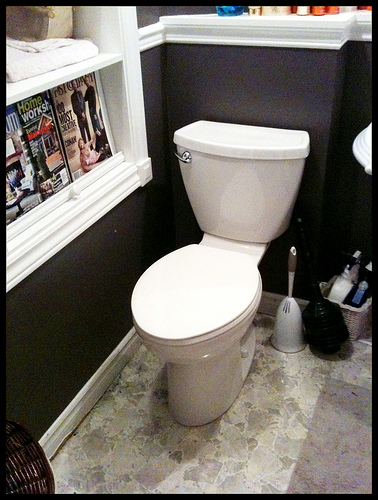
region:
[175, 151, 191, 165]
CROME HANDLE ON THE TOILET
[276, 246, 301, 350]
TOILET BOWL BRUSH CLEANER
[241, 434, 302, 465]
TILE ON THE FLOOR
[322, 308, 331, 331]
BLACK PLUNGIE ON THE FLOOR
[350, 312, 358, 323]
STRAW BASKET ON THE FLOOR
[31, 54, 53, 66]
WHITE TOWEL ON THE SHELF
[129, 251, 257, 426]
A white clean toilet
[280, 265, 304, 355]
A white clean toilet brush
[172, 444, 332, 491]
A white clean toilet floor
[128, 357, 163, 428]
A white clean toilet floor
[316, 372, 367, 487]
A white clean toilet floor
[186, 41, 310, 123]
A green clean toilet wall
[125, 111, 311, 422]
this is a toilet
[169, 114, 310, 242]
this is a water tank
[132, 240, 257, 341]
this is a toilet cover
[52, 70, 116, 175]
this is a magazine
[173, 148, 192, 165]
this is a handle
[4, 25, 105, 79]
this is a towel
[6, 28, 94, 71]
this is a white towel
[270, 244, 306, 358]
this is a toilet brush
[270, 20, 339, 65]
Black wall with white trim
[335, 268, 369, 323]
Bathroom items stored in wicker basket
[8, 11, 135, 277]
White shelf built into wall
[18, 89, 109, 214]
Magazines standing on a built in shelf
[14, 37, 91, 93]
White folded towel on shelf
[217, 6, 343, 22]
Bathroom items lined up on ledge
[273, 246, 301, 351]
Toilet bowl brush in holder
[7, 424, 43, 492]
Edge of wicker basket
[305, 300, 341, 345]
Black plastic toilet plunger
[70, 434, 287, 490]
Linoleum floor with stone design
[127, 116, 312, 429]
White porcelin toilet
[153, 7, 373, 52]
Small white shelf behind the toilet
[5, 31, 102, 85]
Folded towel on the shelf to the left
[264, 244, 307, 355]
Toilet cleaning brush in holder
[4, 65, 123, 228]
Magazines on the left wall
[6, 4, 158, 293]
Built in shelf area on the left wall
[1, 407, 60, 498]
Dark brown wicker basket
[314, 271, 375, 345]
Light colored wicker basket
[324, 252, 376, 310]
Cleaning supplies in the basket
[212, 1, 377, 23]
Bolltles and other things on the shelf behind the toilet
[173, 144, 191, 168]
silver handle on the flush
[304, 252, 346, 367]
black plunger on the floor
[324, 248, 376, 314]
basket full of cleaners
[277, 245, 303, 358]
toliet bowel brush in a holder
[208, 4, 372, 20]
candles on the shelf